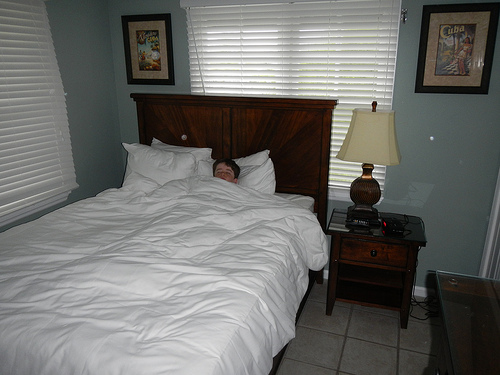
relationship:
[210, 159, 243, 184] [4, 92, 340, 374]
boy in bed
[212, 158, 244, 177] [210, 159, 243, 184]
hair on boy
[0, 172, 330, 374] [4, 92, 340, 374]
bed cover on bed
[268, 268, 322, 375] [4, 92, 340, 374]
frame on bed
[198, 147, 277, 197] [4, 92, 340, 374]
pillow on bed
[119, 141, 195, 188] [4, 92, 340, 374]
pillow on bed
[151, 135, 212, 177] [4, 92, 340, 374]
pillow on bed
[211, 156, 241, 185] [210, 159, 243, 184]
head on boy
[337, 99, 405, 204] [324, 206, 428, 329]
lamp on table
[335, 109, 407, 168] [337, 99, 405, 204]
lampshade on lamp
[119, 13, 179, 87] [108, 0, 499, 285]
picture on wall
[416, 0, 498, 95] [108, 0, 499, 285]
picture on wall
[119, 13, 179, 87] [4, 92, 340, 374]
picture behind bed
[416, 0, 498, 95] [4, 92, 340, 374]
picture behind bed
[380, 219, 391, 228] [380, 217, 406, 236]
numbers on alarm clock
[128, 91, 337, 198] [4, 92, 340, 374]
headboard on bed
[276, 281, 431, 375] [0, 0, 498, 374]
floor in room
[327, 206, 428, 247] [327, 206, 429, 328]
top of nightstand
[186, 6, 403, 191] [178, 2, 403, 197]
window covered mini blinds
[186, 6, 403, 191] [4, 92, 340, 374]
window behind bed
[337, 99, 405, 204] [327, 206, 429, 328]
lamp on nightstand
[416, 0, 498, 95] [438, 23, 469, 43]
picture says cuba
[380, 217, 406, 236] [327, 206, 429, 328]
alarm clock on nightstand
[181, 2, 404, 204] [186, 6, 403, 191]
shade on window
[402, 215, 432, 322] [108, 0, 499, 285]
cord plugged into wall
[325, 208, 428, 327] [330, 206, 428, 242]
dresser with protective layer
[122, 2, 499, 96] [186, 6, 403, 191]
pictures frame window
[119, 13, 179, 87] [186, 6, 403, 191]
picture frames window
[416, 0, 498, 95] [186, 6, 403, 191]
picture frames window